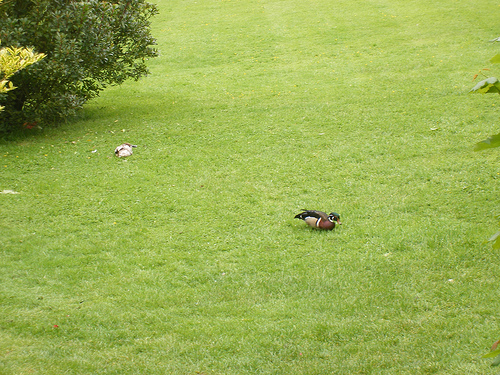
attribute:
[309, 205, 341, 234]
duck — black, green, yellow, looking, sitting, laying, grey, dark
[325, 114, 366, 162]
grass — green, bright, red, thick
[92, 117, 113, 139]
leaves — red, green, yellow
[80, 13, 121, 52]
branch — green, yellow